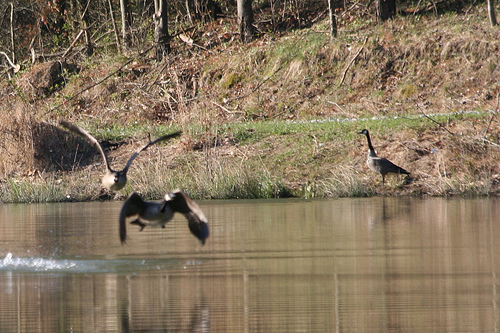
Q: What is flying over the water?
A: There are geese flying over the water.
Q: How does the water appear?
A: The water is calm and reflective.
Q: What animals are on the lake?
A: There are ducks on the lake.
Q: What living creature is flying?
A: Ducks.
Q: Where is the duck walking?
A: Next to the water.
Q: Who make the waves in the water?
A: Ducks.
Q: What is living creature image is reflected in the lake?
A: Duck.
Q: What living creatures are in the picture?
A: Ducks.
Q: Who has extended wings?
A: Duck.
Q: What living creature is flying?
A: Bird.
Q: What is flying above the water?
A: Ducks.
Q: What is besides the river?
A: Embankment.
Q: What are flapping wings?
A: Birds.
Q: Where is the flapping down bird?
A: Front.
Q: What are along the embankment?
A: Tree trunks.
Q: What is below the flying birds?
A: Water.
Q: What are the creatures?
A: Birds.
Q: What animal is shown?
A: Birds.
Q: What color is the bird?
A: Brown.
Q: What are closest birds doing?
A: Flying.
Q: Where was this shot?
A: Pond.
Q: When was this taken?
A: Daytime.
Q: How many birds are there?
A: 3.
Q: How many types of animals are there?
A: 1.